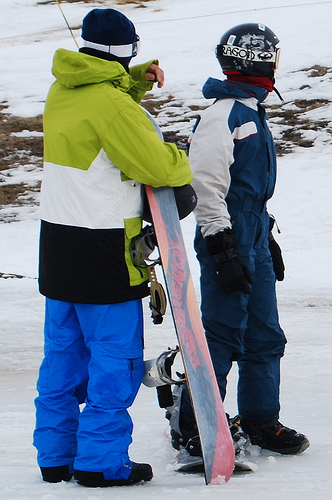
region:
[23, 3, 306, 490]
two people on the mountain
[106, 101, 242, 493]
the man holds onto a board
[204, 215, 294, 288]
this person is wearing black gloves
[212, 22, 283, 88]
this person is wearing a helmet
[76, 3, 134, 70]
the man is wearing a beanie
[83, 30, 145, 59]
he also wears a pair of ski goggles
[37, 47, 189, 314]
the man wears a ski jacket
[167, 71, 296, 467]
this person is wearing a snow suit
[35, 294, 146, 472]
the mans snot pants are blue in color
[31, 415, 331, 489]
both parties wear black boots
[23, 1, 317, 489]
Two people in the foreground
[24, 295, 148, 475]
Person is wearing light blue pants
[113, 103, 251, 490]
A snowboard in the foreground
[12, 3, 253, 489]
Person is holding a snowboard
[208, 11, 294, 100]
Person is wearing a helmet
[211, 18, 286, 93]
The helmet is black in color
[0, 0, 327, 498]
Snow is on the ground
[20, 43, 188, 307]
Man is wearing a hoodie coat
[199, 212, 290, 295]
Man is wearing black gloves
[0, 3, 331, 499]
Photo was taken in the daytime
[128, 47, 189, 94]
the hand of a man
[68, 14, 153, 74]
the head of a man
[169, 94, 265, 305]
the arm of a man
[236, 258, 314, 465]
the leg of a man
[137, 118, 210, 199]
the elbow of a man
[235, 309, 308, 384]
the knee of a man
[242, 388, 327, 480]
the foot of a man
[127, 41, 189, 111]
the fingers of a man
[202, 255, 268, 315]
a man wearing gloves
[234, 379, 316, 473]
a man wearing shoes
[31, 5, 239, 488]
A person holding a snowboard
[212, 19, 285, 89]
A helmet on a person's head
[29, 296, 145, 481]
A pair of blue ski pants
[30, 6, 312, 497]
Two people standing on the snow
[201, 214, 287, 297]
A pair of black gloves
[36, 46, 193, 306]
A green, white and black jacket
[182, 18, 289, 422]
A blue and white snow outfit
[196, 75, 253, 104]
Blue hood on a jacket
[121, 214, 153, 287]
Green pocket on a jacket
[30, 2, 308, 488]
the people standing in the snow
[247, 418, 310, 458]
the black boot on the foot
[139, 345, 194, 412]
the strap on the snowboard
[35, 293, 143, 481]
the bright blue pair of pants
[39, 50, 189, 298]
the green, white and black jacket on the man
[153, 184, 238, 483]
the snowboard under the mans arm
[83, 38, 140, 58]
the white strap on the back of the mans head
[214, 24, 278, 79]
the balck helmet on the head of the man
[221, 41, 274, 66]
the white strap of the googles on the helmet